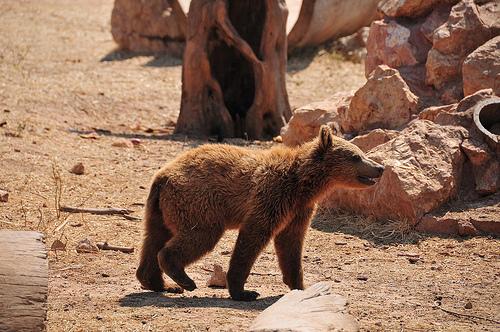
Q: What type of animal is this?
A: Bear.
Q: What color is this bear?
A: Brown.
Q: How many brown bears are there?
A: 1.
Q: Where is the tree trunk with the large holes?
A: Behind the bear.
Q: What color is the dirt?
A: Light brown.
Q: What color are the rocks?
A: Reddish.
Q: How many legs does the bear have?
A: 4.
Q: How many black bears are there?
A: None.